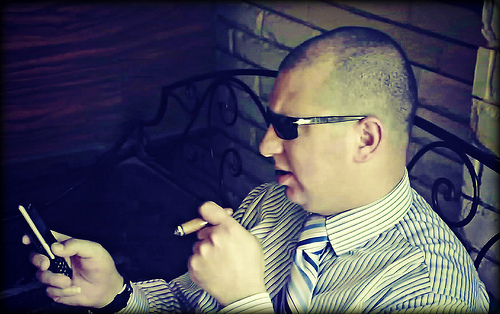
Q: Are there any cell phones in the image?
A: Yes, there is a cell phone.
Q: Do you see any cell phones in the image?
A: Yes, there is a cell phone.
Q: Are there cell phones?
A: Yes, there is a cell phone.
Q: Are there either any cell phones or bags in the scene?
A: Yes, there is a cell phone.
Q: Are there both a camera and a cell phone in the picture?
A: No, there is a cell phone but no cameras.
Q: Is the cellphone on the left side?
A: Yes, the cellphone is on the left of the image.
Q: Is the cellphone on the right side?
A: No, the cellphone is on the left of the image.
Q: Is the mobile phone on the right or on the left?
A: The mobile phone is on the left of the image.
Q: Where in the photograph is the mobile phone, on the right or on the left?
A: The mobile phone is on the left of the image.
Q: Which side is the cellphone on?
A: The cellphone is on the left of the image.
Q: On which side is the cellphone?
A: The cellphone is on the left of the image.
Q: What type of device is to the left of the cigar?
A: The device is a cell phone.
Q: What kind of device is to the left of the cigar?
A: The device is a cell phone.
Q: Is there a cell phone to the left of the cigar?
A: Yes, there is a cell phone to the left of the cigar.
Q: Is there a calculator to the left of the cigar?
A: No, there is a cell phone to the left of the cigar.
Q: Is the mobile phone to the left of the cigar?
A: Yes, the mobile phone is to the left of the cigar.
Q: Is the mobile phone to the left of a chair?
A: No, the mobile phone is to the left of the cigar.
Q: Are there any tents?
A: No, there are no tents.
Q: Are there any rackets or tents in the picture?
A: No, there are no tents or rackets.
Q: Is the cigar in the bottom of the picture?
A: Yes, the cigar is in the bottom of the image.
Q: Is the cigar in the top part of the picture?
A: No, the cigar is in the bottom of the image.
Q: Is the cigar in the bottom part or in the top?
A: The cigar is in the bottom of the image.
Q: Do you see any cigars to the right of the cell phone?
A: Yes, there is a cigar to the right of the cell phone.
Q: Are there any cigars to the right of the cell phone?
A: Yes, there is a cigar to the right of the cell phone.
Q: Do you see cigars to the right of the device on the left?
A: Yes, there is a cigar to the right of the cell phone.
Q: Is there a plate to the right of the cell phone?
A: No, there is a cigar to the right of the cell phone.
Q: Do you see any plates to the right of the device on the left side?
A: No, there is a cigar to the right of the cell phone.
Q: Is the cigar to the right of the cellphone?
A: Yes, the cigar is to the right of the cellphone.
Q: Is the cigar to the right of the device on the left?
A: Yes, the cigar is to the right of the cellphone.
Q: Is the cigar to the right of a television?
A: No, the cigar is to the right of the cellphone.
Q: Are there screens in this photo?
A: No, there are no screens.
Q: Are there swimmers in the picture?
A: No, there are no swimmers.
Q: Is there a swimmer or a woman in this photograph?
A: No, there are no swimmers or women.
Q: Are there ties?
A: Yes, there is a tie.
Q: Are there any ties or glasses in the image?
A: Yes, there is a tie.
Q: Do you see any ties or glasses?
A: Yes, there is a tie.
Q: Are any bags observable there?
A: No, there are no bags.